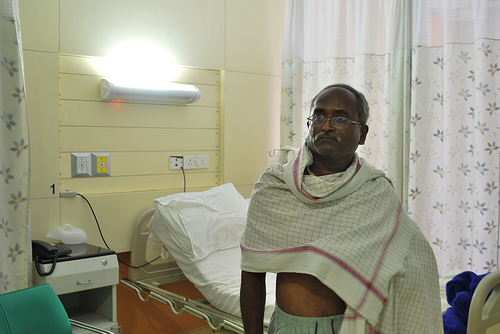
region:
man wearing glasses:
[295, 114, 373, 144]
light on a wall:
[88, 54, 223, 116]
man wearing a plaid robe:
[263, 157, 429, 289]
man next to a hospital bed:
[198, 215, 299, 322]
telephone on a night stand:
[27, 221, 65, 271]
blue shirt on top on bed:
[427, 249, 469, 311]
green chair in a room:
[12, 280, 78, 325]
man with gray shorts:
[250, 290, 295, 322]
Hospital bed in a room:
[113, 165, 258, 321]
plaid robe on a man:
[252, 139, 418, 281]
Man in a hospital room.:
[15, 6, 490, 327]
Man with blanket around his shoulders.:
[237, 78, 453, 325]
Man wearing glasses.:
[286, 74, 379, 179]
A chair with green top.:
[3, 277, 90, 332]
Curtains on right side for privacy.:
[281, 4, 493, 285]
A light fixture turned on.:
[76, 61, 206, 106]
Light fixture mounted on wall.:
[89, 73, 201, 110]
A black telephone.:
[21, 225, 77, 275]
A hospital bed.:
[131, 187, 271, 319]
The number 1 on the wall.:
[46, 175, 61, 202]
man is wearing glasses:
[285, 85, 393, 157]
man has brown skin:
[277, 71, 382, 157]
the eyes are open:
[297, 107, 359, 137]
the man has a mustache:
[305, 124, 349, 149]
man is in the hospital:
[55, 32, 483, 327]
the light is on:
[72, 20, 211, 110]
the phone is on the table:
[0, 223, 86, 273]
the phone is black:
[1, 225, 88, 276]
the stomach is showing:
[254, 261, 343, 321]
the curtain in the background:
[235, 5, 492, 260]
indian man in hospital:
[224, 62, 454, 332]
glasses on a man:
[301, 109, 366, 136]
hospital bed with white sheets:
[122, 179, 257, 313]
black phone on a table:
[23, 230, 79, 274]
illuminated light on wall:
[91, 63, 213, 116]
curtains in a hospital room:
[400, 30, 498, 232]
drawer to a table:
[42, 245, 132, 300]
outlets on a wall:
[165, 146, 215, 174]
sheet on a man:
[271, 171, 424, 278]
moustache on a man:
[307, 130, 350, 144]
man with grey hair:
[350, 87, 372, 117]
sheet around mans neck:
[324, 223, 383, 248]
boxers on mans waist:
[266, 318, 294, 333]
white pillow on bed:
[177, 203, 219, 234]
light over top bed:
[93, 35, 193, 80]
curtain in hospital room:
[435, 78, 489, 166]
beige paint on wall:
[238, 93, 264, 133]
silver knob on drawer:
[72, 271, 99, 292]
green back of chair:
[16, 299, 51, 319]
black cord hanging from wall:
[83, 205, 111, 235]